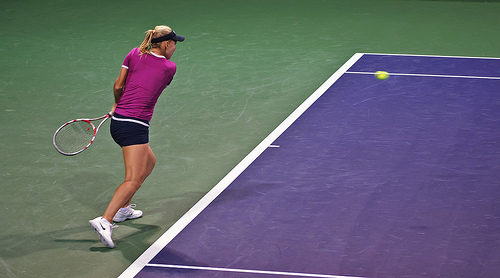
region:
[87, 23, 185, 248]
Lady tennis player preparing to hit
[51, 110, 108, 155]
Red and gray tennis racket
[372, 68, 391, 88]
Yellow tennis ball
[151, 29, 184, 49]
Black visor on lady tennis player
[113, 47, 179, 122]
Purple shirt on lady tennis player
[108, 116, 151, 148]
Black short on lady tennis player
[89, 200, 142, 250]
White nike tennis shoes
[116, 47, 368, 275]
Baseline on a tennis court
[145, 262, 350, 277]
Sideline on a tennis court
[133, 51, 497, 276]
Blue tennis court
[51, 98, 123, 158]
tennis racket in swinging motion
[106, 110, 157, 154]
woman's blue short shorts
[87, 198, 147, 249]
pair of nike shoes on the green ground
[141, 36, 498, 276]
tennis playing field area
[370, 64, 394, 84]
incoming tennis ball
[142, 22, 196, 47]
dark cap on young woman's head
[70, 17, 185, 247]
tennis player ready to strike the ball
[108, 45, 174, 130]
bright pink woman's shirt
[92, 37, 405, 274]
white line separating the purple and green area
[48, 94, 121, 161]
tennis racket with blue and white colors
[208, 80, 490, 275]
A purple tennis court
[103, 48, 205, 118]
a raspberry colored t-shirt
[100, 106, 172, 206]
a lady wears black shorts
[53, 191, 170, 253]
A pair of white Nike's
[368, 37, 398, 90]
a yellow tennis ball in motion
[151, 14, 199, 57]
a black sun visor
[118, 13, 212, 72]
a blond lady wearing a pony tail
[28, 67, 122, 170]
a red striped tennis racquet.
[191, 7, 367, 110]
A green tennis court cover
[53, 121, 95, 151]
netting on a tennis racquet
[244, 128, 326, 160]
small line on court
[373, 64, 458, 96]
yellow tennis ball in the air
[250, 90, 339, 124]
bold tennis court edge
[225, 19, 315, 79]
green asphalt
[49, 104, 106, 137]
red lines in tennis court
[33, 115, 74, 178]
silver edge on tennis court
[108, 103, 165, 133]
white edge on short black short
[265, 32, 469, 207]
purple tennis court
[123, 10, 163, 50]
pony tail in woman's hair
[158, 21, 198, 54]
black sun visor on woman's head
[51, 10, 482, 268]
person playing tennis on court.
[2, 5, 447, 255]
woman playing tennis on court.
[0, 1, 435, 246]
lady playing tennis on court.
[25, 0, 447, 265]
young lady playing tennis on court.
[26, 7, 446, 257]
lady striking tennis ball on court.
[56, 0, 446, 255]
young lady striking tennis ball on court.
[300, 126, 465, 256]
purple patch of tennis court.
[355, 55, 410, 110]
tennis ball off in motion.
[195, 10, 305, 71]
green patch of tennis court.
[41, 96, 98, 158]
tennis racquet in view.